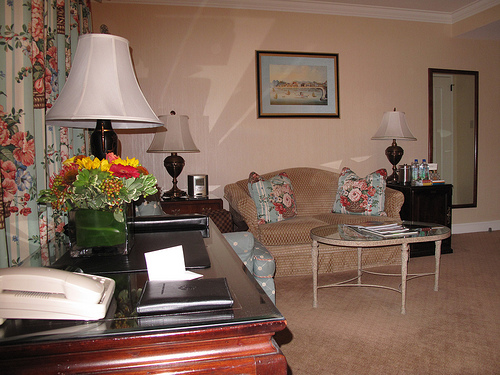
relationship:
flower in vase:
[109, 163, 141, 178] [72, 209, 127, 246]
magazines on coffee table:
[353, 218, 420, 240] [308, 217, 453, 318]